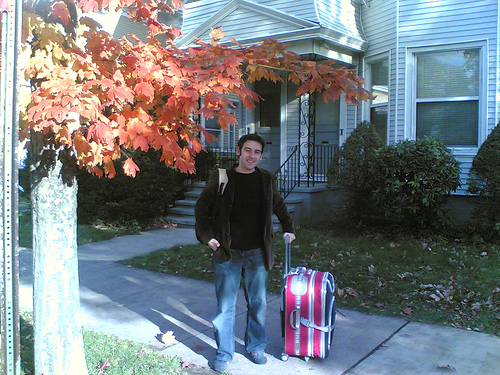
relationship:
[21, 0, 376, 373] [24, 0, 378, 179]
tree has leaves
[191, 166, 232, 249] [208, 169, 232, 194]
backpack on shoulder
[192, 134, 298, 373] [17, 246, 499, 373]
man standing on sidewalk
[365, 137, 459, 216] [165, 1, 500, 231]
bush next to house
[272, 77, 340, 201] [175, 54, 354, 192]
railing on porch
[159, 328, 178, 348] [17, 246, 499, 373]
leaf on sidewalk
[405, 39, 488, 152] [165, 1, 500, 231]
window on house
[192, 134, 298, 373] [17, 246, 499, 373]
man on sidewalk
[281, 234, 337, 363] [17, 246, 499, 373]
suitcase on sidewalk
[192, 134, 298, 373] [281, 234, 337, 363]
man next to suitcase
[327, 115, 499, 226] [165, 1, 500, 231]
bushes in front of house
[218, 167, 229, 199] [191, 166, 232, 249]
strap of backpack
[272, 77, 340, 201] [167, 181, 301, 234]
railing on stairs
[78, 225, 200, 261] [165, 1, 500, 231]
pathway leads to house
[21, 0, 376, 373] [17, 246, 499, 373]
tree on sidewalk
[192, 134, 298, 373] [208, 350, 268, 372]
man wearing shoes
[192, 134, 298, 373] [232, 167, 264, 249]
man wearing shirt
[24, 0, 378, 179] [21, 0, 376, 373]
leaves on tree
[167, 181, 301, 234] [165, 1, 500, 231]
stairs leading to house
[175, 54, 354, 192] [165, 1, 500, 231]
porch on house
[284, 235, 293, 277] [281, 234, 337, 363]
handle on suitcase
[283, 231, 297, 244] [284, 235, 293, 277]
hand on handle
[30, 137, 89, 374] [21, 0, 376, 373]
trunk on tree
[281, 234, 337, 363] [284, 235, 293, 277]
suitcase has handle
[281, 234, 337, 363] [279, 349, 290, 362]
suitcase has wheels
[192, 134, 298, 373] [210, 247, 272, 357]
man wearing jeans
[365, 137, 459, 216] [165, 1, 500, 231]
bush in front of house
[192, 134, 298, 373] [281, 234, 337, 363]
man holding suitcase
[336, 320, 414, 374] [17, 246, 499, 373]
line in sidewalk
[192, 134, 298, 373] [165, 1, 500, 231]
man in front of house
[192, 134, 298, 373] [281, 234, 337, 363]
man with suitcase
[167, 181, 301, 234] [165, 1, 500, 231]
stairs on house